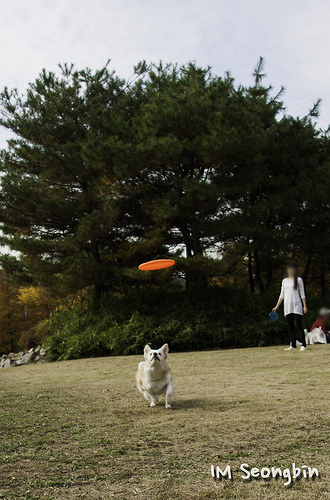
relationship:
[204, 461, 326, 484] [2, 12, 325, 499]
watermark on picture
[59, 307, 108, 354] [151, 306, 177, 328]
bushes are thick and green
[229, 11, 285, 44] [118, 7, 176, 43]
sky cloudy and blue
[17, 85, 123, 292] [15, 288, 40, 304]
tree with yellow leaf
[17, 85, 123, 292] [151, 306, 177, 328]
tree tall and green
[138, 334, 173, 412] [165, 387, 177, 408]
dog has left paw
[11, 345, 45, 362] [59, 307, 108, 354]
rocks near bushes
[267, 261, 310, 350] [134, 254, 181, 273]
woman holding frisbee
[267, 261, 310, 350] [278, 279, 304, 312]
woman wearing white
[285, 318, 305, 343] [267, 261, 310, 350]
black pants on woman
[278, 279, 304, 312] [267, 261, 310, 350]
white shoes on woman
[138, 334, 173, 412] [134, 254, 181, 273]
dog jumping for frisbee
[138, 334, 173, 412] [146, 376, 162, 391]
dog ears are beige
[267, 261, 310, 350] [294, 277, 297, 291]
woman has dark hair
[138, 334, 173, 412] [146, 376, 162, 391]
dog small and beige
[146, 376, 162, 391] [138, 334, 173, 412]
beige ear on dog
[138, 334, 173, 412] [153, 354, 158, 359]
dog has a black nose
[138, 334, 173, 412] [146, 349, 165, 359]
dog has black eyes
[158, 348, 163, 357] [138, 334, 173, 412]
eye on dog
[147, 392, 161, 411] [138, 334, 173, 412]
leg of dog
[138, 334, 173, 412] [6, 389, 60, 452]
dog playing on grass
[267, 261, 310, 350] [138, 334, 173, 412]
woman playing with dog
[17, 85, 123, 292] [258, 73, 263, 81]
tree has green leaves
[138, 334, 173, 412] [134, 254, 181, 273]
dog chasing frisbee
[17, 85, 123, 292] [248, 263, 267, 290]
tree has trunk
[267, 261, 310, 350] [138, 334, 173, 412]
woman relaxing with dog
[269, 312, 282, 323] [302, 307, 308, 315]
frisbee in womans hand